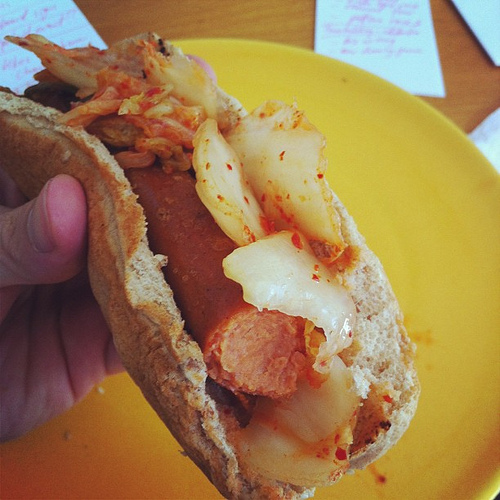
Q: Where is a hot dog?
A: In a bun.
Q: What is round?
A: Plate.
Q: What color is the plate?
A: Yellow.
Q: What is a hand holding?
A: A hot dog.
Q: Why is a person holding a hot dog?
A: To eat it.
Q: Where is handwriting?
A: On white paper.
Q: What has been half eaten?
A: The hot dog.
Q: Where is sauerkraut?
A: On the hot dog.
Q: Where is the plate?
A: On a table.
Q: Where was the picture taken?
A: At a table.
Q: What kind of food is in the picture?
A: A hot dog.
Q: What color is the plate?
A: Yellow.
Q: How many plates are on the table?
A: 1.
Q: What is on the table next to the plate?
A: Paper.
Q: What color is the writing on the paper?
A: Pink.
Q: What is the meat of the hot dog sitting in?
A: A bun.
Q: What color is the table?
A: Brown.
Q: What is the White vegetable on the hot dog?
A: Onion.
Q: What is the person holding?
A: A hotdog.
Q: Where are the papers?
A: On the table.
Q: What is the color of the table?
A: Brown.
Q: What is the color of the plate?
A: Yellow.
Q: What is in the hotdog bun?
A: Onions and hotdog.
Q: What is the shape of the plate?
A: Round.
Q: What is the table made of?
A: Wood.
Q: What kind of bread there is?
A: Wheat.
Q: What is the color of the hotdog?
A: Brown.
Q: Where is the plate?
A: On the table.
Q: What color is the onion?
A: White.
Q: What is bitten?
A: The hot dog.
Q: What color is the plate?
A: Yellow.